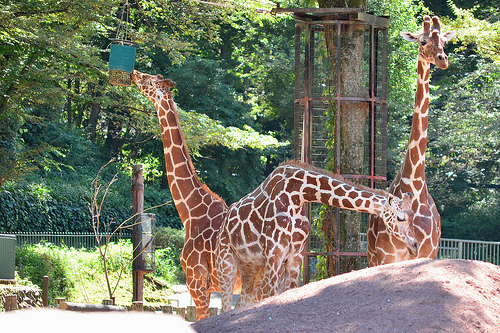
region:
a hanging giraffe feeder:
[103, 35, 137, 93]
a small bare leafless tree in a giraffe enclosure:
[84, 153, 170, 302]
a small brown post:
[38, 273, 53, 304]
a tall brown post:
[127, 160, 148, 308]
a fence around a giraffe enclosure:
[2, 227, 133, 270]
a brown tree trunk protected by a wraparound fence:
[320, 0, 376, 277]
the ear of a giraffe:
[398, 27, 415, 45]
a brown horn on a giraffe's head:
[422, 12, 431, 33]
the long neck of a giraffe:
[153, 99, 207, 213]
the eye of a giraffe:
[419, 36, 430, 46]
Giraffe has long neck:
[133, 65, 301, 299]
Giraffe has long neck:
[218, 172, 420, 299]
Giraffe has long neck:
[373, 21, 457, 269]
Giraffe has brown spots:
[136, 68, 297, 315]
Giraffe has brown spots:
[222, 167, 422, 294]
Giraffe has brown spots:
[373, 25, 458, 257]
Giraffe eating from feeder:
[112, 43, 264, 320]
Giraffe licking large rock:
[216, 165, 424, 306]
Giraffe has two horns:
[393, 8, 456, 263]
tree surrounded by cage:
[276, 2, 381, 266]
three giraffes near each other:
[142, 25, 452, 272]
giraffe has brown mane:
[280, 152, 382, 197]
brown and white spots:
[212, 162, 381, 274]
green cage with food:
[95, 44, 126, 78]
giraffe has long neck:
[146, 77, 216, 261]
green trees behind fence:
[47, 24, 498, 209]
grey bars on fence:
[6, 230, 499, 281]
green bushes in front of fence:
[18, 221, 188, 306]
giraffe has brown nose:
[418, 42, 455, 79]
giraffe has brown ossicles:
[420, 12, 437, 35]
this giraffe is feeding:
[100, 30, 244, 324]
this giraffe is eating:
[110, 27, 243, 322]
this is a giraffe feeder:
[99, 8, 150, 94]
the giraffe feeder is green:
[98, 5, 163, 114]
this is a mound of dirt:
[220, 241, 497, 331]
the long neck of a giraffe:
[397, 54, 438, 183]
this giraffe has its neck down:
[209, 146, 429, 315]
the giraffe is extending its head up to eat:
[108, 52, 231, 307]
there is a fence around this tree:
[287, 5, 404, 282]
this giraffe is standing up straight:
[364, 10, 487, 280]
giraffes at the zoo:
[98, 28, 416, 308]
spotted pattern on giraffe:
[189, 193, 290, 238]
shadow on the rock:
[212, 305, 459, 325]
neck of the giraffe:
[403, 54, 433, 189]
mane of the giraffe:
[264, 156, 384, 197]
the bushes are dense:
[70, 189, 143, 231]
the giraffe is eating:
[97, 59, 173, 111]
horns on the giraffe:
[422, 15, 442, 39]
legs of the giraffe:
[255, 257, 315, 292]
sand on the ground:
[37, 313, 146, 328]